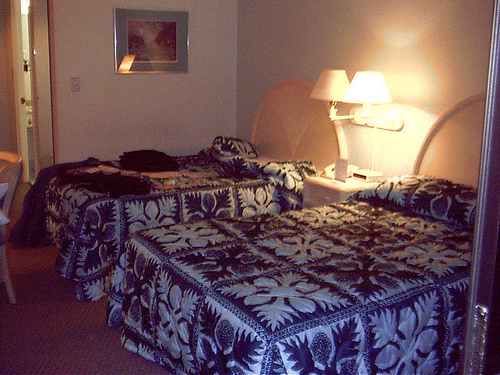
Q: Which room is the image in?
A: It is at the bedroom.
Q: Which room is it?
A: It is a bedroom.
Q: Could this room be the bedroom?
A: Yes, it is the bedroom.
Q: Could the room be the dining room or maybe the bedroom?
A: It is the bedroom.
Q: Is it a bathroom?
A: No, it is a bedroom.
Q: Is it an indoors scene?
A: Yes, it is indoors.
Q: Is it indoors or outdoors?
A: It is indoors.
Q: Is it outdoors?
A: No, it is indoors.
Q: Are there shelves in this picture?
A: No, there are no shelves.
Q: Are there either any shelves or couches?
A: No, there are no shelves or couches.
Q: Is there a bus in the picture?
A: Yes, there is a bus.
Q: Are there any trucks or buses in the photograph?
A: Yes, there is a bus.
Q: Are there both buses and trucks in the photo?
A: No, there is a bus but no trucks.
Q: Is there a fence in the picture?
A: No, there are no fences.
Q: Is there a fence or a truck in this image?
A: No, there are no fences or trucks.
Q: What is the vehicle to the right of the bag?
A: The vehicle is a bus.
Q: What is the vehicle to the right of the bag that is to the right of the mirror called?
A: The vehicle is a bus.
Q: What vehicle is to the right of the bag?
A: The vehicle is a bus.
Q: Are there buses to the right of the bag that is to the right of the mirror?
A: Yes, there is a bus to the right of the bag.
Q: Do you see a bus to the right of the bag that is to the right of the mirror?
A: Yes, there is a bus to the right of the bag.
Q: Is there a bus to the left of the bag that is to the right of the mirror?
A: No, the bus is to the right of the bag.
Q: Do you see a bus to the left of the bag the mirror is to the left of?
A: No, the bus is to the right of the bag.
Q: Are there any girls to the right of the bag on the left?
A: No, there is a bus to the right of the bag.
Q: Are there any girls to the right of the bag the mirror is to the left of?
A: No, there is a bus to the right of the bag.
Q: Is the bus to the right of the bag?
A: Yes, the bus is to the right of the bag.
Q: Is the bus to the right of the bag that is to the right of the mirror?
A: Yes, the bus is to the right of the bag.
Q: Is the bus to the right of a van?
A: No, the bus is to the right of the bag.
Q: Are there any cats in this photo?
A: No, there are no cats.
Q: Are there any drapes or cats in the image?
A: No, there are no cats or drapes.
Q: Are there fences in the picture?
A: No, there are no fences.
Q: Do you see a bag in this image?
A: Yes, there is a bag.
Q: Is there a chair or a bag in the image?
A: Yes, there is a bag.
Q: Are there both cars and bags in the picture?
A: No, there is a bag but no cars.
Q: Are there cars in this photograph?
A: No, there are no cars.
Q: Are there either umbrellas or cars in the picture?
A: No, there are no cars or umbrellas.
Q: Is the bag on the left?
A: Yes, the bag is on the left of the image.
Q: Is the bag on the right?
A: No, the bag is on the left of the image.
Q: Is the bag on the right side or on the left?
A: The bag is on the left of the image.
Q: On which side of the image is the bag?
A: The bag is on the left of the image.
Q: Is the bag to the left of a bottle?
A: No, the bag is to the left of the bus.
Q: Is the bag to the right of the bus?
A: No, the bag is to the left of the bus.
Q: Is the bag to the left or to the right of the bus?
A: The bag is to the left of the bus.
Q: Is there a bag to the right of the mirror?
A: Yes, there is a bag to the right of the mirror.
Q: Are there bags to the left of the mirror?
A: No, the bag is to the right of the mirror.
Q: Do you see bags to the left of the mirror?
A: No, the bag is to the right of the mirror.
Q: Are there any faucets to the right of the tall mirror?
A: No, there is a bag to the right of the mirror.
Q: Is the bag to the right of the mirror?
A: Yes, the bag is to the right of the mirror.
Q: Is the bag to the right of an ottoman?
A: No, the bag is to the right of the mirror.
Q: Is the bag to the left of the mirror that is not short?
A: No, the bag is to the right of the mirror.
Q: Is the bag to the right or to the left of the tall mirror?
A: The bag is to the right of the mirror.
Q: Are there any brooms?
A: No, there are no brooms.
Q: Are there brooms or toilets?
A: No, there are no brooms or toilets.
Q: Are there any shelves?
A: No, there are no shelves.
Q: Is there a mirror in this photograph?
A: Yes, there is a mirror.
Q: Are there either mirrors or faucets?
A: Yes, there is a mirror.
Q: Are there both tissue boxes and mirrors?
A: No, there is a mirror but no tissue boxes.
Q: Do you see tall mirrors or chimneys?
A: Yes, there is a tall mirror.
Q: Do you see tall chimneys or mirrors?
A: Yes, there is a tall mirror.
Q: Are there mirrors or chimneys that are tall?
A: Yes, the mirror is tall.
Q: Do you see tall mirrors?
A: Yes, there is a tall mirror.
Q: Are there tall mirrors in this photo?
A: Yes, there is a tall mirror.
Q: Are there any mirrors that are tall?
A: Yes, there is a mirror that is tall.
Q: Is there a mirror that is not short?
A: Yes, there is a tall mirror.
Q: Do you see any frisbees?
A: No, there are no frisbees.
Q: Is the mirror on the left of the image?
A: Yes, the mirror is on the left of the image.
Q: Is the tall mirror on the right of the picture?
A: No, the mirror is on the left of the image.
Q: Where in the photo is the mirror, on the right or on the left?
A: The mirror is on the left of the image.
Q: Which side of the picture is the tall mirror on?
A: The mirror is on the left of the image.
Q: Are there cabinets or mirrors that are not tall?
A: No, there is a mirror but it is tall.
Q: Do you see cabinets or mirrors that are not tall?
A: No, there is a mirror but it is tall.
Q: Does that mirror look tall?
A: Yes, the mirror is tall.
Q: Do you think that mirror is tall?
A: Yes, the mirror is tall.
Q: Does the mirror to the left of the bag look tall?
A: Yes, the mirror is tall.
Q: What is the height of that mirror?
A: The mirror is tall.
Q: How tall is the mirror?
A: The mirror is tall.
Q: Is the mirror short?
A: No, the mirror is tall.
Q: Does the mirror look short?
A: No, the mirror is tall.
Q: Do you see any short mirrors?
A: No, there is a mirror but it is tall.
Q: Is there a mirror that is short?
A: No, there is a mirror but it is tall.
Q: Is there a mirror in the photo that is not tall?
A: No, there is a mirror but it is tall.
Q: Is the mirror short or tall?
A: The mirror is tall.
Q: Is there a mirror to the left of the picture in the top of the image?
A: Yes, there is a mirror to the left of the picture.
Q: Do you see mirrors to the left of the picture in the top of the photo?
A: Yes, there is a mirror to the left of the picture.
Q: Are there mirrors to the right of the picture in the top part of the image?
A: No, the mirror is to the left of the picture.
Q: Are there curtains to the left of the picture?
A: No, there is a mirror to the left of the picture.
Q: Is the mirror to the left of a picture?
A: Yes, the mirror is to the left of a picture.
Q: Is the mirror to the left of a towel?
A: No, the mirror is to the left of a picture.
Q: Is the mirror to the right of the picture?
A: No, the mirror is to the left of the picture.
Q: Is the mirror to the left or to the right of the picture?
A: The mirror is to the left of the picture.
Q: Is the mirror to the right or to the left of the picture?
A: The mirror is to the left of the picture.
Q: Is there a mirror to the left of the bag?
A: Yes, there is a mirror to the left of the bag.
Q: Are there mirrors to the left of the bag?
A: Yes, there is a mirror to the left of the bag.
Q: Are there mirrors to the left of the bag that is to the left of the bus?
A: Yes, there is a mirror to the left of the bag.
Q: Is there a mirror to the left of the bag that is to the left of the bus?
A: Yes, there is a mirror to the left of the bag.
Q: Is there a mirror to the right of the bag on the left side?
A: No, the mirror is to the left of the bag.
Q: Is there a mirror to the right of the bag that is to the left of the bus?
A: No, the mirror is to the left of the bag.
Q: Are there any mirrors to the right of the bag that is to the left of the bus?
A: No, the mirror is to the left of the bag.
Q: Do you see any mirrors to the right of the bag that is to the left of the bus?
A: No, the mirror is to the left of the bag.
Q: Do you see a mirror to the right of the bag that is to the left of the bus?
A: No, the mirror is to the left of the bag.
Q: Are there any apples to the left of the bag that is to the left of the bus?
A: No, there is a mirror to the left of the bag.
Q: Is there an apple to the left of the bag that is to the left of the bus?
A: No, there is a mirror to the left of the bag.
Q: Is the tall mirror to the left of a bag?
A: Yes, the mirror is to the left of a bag.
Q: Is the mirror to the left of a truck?
A: No, the mirror is to the left of a bag.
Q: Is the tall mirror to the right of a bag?
A: No, the mirror is to the left of a bag.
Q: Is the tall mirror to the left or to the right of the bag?
A: The mirror is to the left of the bag.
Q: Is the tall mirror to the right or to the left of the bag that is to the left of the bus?
A: The mirror is to the left of the bag.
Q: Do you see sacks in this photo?
A: No, there are no sacks.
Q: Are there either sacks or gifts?
A: No, there are no sacks or gifts.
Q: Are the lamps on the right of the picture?
A: Yes, the lamps are on the right of the image.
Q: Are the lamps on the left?
A: No, the lamps are on the right of the image.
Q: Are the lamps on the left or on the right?
A: The lamps are on the right of the image.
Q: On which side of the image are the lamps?
A: The lamps are on the right of the image.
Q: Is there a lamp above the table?
A: Yes, there are lamps above the table.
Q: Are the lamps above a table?
A: Yes, the lamps are above a table.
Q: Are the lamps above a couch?
A: No, the lamps are above a table.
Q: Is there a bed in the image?
A: Yes, there is a bed.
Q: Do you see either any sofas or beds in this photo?
A: Yes, there is a bed.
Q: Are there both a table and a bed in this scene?
A: Yes, there are both a bed and a table.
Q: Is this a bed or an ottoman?
A: This is a bed.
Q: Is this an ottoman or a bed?
A: This is a bed.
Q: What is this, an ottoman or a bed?
A: This is a bed.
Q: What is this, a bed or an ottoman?
A: This is a bed.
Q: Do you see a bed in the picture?
A: Yes, there is a bed.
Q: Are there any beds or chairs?
A: Yes, there is a bed.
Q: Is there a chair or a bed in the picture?
A: Yes, there is a bed.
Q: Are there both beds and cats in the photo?
A: No, there is a bed but no cats.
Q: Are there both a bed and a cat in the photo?
A: No, there is a bed but no cats.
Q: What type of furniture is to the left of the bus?
A: The piece of furniture is a bed.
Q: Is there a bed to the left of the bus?
A: Yes, there is a bed to the left of the bus.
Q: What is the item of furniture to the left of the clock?
A: The piece of furniture is a bed.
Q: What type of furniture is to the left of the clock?
A: The piece of furniture is a bed.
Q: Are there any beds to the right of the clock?
A: No, the bed is to the left of the clock.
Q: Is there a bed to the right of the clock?
A: No, the bed is to the left of the clock.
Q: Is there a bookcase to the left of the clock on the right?
A: No, there is a bed to the left of the clock.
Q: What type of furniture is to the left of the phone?
A: The piece of furniture is a bed.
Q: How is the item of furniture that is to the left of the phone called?
A: The piece of furniture is a bed.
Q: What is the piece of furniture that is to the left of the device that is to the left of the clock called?
A: The piece of furniture is a bed.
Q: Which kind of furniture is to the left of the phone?
A: The piece of furniture is a bed.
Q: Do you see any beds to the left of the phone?
A: Yes, there is a bed to the left of the phone.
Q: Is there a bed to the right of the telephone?
A: No, the bed is to the left of the telephone.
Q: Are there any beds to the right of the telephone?
A: No, the bed is to the left of the telephone.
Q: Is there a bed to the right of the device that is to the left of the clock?
A: No, the bed is to the left of the telephone.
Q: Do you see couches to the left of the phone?
A: No, there is a bed to the left of the phone.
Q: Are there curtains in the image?
A: No, there are no curtains.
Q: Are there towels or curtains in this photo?
A: No, there are no curtains or towels.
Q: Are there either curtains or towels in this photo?
A: No, there are no curtains or towels.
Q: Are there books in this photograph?
A: No, there are no books.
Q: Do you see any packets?
A: No, there are no packets.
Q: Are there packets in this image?
A: No, there are no packets.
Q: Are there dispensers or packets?
A: No, there are no packets or dispensers.